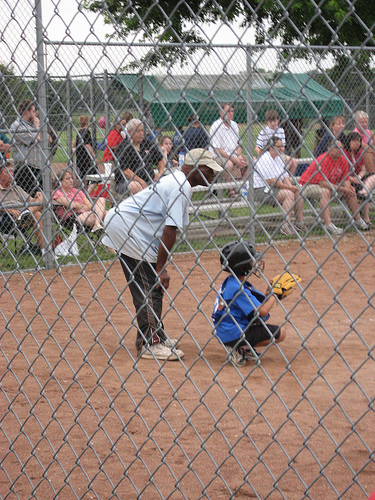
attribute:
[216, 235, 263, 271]
helmet — black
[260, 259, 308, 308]
glove — yellow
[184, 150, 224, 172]
cap — beige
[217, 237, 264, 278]
helmet — black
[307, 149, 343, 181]
shirt — red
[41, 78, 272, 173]
people — watching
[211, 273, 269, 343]
shirt — blue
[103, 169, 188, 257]
shirt — white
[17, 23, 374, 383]
fence — metal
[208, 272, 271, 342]
shirt — blue, short sleeved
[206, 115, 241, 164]
shirt — white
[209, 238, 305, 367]
boy — catcher